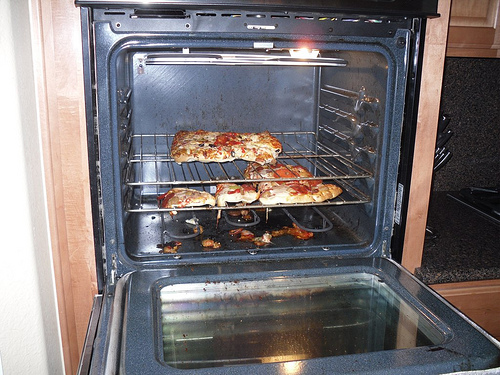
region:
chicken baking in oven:
[161, 125, 285, 169]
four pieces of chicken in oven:
[151, 122, 326, 214]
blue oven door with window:
[83, 275, 468, 316]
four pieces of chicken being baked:
[142, 114, 349, 213]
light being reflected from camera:
[279, 39, 331, 74]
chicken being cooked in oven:
[126, 110, 336, 212]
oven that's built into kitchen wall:
[0, 74, 472, 335]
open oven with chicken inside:
[101, 18, 418, 345]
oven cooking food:
[97, 62, 482, 339]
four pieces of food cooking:
[131, 52, 377, 307]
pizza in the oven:
[155, 120, 304, 175]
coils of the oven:
[148, 191, 343, 241]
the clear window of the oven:
[125, 265, 442, 363]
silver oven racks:
[110, 102, 373, 250]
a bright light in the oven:
[284, 35, 341, 80]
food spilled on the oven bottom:
[154, 214, 331, 261]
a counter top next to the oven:
[431, 204, 480, 283]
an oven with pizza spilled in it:
[80, 16, 492, 369]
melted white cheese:
[225, 142, 281, 161]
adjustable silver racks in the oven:
[120, 130, 380, 232]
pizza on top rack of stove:
[165, 112, 294, 168]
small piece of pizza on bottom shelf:
[158, 174, 213, 216]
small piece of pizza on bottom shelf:
[210, 167, 260, 210]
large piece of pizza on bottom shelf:
[242, 160, 362, 203]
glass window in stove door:
[134, 268, 398, 373]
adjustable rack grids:
[312, 73, 381, 208]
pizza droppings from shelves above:
[152, 215, 327, 260]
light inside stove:
[283, 41, 325, 71]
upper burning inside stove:
[145, 43, 352, 78]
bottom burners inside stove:
[157, 204, 337, 239]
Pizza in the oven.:
[156, 118, 340, 209]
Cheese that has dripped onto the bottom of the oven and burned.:
[155, 213, 315, 257]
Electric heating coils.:
[164, 210, 336, 239]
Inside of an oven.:
[75, 1, 415, 263]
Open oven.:
[77, 3, 397, 260]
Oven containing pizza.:
[90, 9, 390, 260]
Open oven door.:
[76, 252, 498, 374]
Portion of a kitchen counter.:
[412, 190, 497, 283]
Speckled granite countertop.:
[416, 186, 497, 282]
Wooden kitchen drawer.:
[432, 281, 497, 338]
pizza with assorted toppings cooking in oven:
[174, 130, 214, 155]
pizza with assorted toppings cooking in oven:
[219, 134, 239, 153]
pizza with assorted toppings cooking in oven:
[242, 128, 272, 158]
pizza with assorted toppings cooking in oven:
[158, 183, 217, 219]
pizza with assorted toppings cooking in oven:
[207, 174, 249, 209]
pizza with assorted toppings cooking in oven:
[252, 168, 290, 189]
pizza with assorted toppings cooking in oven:
[282, 164, 319, 203]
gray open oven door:
[150, 266, 435, 373]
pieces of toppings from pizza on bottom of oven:
[161, 238, 180, 253]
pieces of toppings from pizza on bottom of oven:
[237, 225, 267, 245]